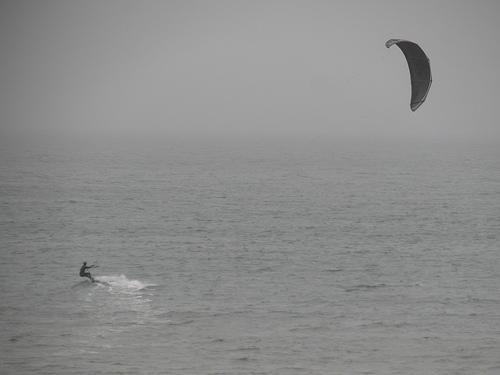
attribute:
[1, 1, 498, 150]
sky — gray, grey, overcast, hazy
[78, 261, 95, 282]
person — sea surfing, wind surfer, wind surfing, kite surfer, leaning back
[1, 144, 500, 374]
ocean — calm, splashy, splash, grey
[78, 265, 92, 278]
wet suit — black